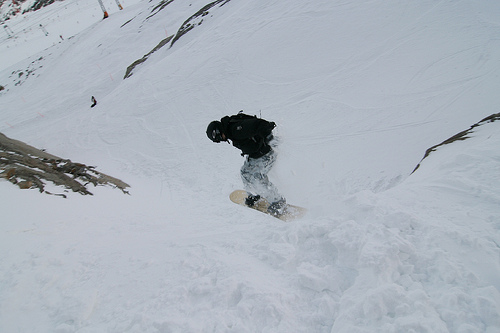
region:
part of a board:
[281, 187, 306, 232]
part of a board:
[233, 178, 243, 188]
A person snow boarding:
[182, 89, 319, 245]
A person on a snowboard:
[201, 103, 325, 245]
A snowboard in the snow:
[214, 178, 322, 229]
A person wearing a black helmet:
[201, 108, 231, 147]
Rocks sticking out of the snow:
[5, 132, 145, 217]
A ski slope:
[20, 52, 460, 247]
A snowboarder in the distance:
[76, 88, 112, 113]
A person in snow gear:
[199, 88, 327, 250]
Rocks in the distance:
[111, 29, 203, 87]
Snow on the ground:
[188, 228, 451, 321]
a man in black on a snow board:
[204, 111, 311, 226]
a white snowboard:
[228, 189, 310, 222]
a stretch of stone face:
[0, 130, 131, 198]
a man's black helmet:
[205, 122, 225, 144]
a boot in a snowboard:
[244, 192, 261, 206]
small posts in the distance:
[97, 0, 124, 19]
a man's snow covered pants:
[237, 153, 286, 199]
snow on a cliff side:
[4, 219, 485, 331]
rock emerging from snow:
[410, 110, 498, 174]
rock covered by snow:
[116, 0, 243, 78]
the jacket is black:
[223, 108, 293, 159]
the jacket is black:
[210, 97, 264, 155]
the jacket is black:
[224, 108, 262, 143]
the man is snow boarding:
[141, 75, 326, 267]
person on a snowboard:
[200, 102, 313, 232]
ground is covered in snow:
[2, 5, 497, 325]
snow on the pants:
[230, 155, 277, 205]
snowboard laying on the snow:
[225, 185, 310, 221]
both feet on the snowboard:
[231, 176, 286, 213]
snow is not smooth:
[202, 201, 487, 328]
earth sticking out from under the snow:
[0, 126, 126, 206]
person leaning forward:
[205, 105, 301, 211]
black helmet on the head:
[202, 120, 217, 140]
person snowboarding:
[200, 110, 313, 225]